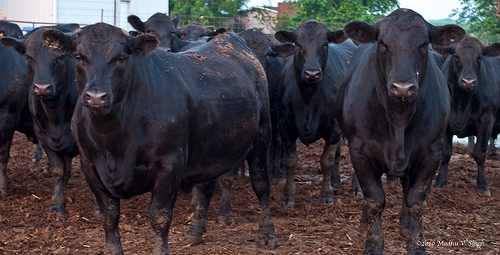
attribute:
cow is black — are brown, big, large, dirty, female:
[342, 6, 464, 252]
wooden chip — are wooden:
[340, 231, 353, 243]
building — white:
[239, 2, 281, 41]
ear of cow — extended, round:
[127, 31, 160, 58]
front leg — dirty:
[150, 165, 176, 254]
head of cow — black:
[271, 9, 351, 86]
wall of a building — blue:
[1, 1, 177, 27]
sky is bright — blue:
[401, 2, 458, 16]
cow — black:
[25, 11, 184, 243]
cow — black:
[278, 14, 403, 204]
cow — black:
[343, 9, 465, 251]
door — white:
[1, 0, 57, 30]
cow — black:
[42, 22, 280, 250]